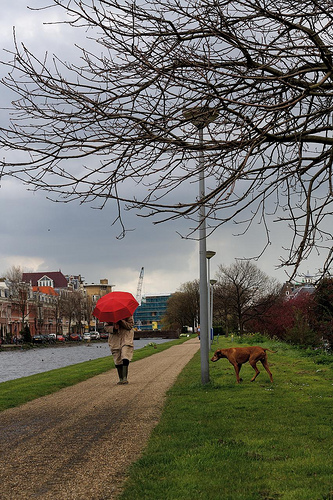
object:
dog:
[209, 345, 279, 387]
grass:
[121, 332, 332, 500]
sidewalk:
[0, 332, 203, 498]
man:
[102, 315, 136, 385]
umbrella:
[91, 290, 139, 326]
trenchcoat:
[103, 313, 135, 348]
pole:
[197, 126, 210, 387]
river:
[0, 337, 161, 387]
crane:
[135, 266, 146, 308]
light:
[181, 95, 222, 132]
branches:
[0, 141, 97, 170]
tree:
[0, 0, 333, 357]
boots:
[121, 364, 129, 384]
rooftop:
[99, 278, 109, 284]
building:
[132, 295, 183, 333]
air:
[34, 29, 87, 53]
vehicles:
[82, 331, 91, 341]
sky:
[0, 0, 333, 306]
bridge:
[133, 329, 179, 339]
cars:
[57, 335, 65, 342]